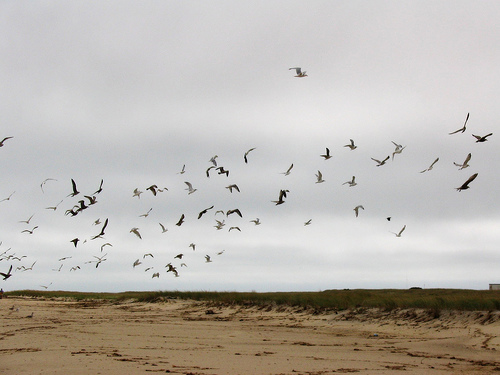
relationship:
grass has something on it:
[372, 284, 446, 317] [410, 282, 431, 299]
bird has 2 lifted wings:
[263, 48, 340, 94] [1, 264, 23, 297]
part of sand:
[425, 341, 448, 356] [0, 296, 500, 373]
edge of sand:
[4, 304, 12, 345] [0, 296, 500, 373]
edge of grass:
[4, 304, 12, 345] [372, 284, 446, 317]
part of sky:
[425, 341, 448, 356] [149, 21, 208, 46]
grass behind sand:
[372, 284, 446, 317] [389, 341, 423, 345]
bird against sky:
[263, 48, 340, 94] [149, 21, 208, 46]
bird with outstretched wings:
[367, 153, 393, 172] [433, 117, 477, 134]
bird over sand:
[263, 48, 340, 94] [389, 341, 423, 345]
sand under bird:
[389, 341, 423, 345] [263, 48, 340, 94]